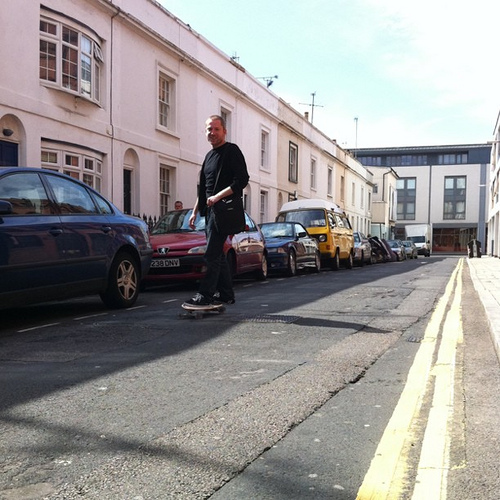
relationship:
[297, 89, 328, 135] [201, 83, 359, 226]
antenna on roof